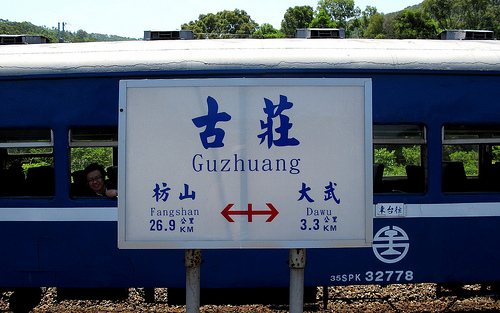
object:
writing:
[142, 88, 356, 238]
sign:
[116, 75, 390, 304]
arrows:
[217, 197, 281, 225]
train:
[1, 25, 498, 292]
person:
[77, 160, 119, 197]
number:
[326, 266, 419, 283]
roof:
[1, 32, 499, 68]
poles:
[168, 245, 326, 311]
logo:
[372, 225, 413, 263]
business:
[52, 19, 78, 36]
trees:
[1, 5, 494, 37]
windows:
[0, 120, 500, 201]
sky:
[10, 1, 398, 18]